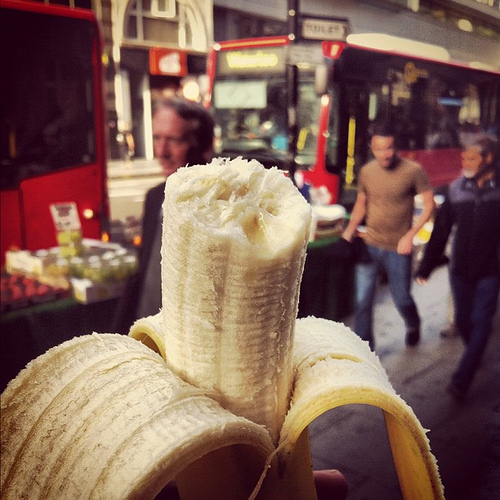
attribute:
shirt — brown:
[353, 154, 423, 256]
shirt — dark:
[415, 173, 498, 279]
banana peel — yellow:
[0, 308, 450, 498]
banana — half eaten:
[162, 165, 312, 430]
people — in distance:
[420, 137, 498, 397]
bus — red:
[197, 33, 498, 223]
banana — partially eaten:
[136, 101, 382, 457]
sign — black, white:
[296, 17, 349, 41]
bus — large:
[226, 29, 485, 181]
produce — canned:
[17, 235, 130, 296]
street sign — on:
[300, 12, 349, 40]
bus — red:
[1, 0, 104, 264]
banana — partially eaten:
[9, 145, 466, 497]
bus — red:
[189, 29, 483, 206]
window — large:
[216, 75, 332, 156]